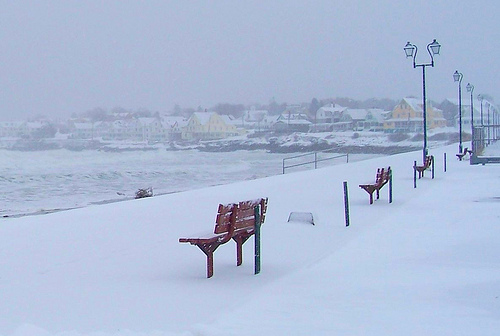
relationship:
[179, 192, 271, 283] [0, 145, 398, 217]
bench near water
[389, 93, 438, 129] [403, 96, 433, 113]
house covered in snow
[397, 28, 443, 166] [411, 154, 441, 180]
lampost by bench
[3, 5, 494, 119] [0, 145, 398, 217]
sky above water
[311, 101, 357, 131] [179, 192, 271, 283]
building not near bench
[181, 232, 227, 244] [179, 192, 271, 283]
snow on bench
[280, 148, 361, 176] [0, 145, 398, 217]
rail near water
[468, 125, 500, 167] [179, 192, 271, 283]
fence near bench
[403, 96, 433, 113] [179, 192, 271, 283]
snow on bench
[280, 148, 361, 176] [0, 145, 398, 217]
rail by water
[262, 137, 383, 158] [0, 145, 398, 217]
rocks are near water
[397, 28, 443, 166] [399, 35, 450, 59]
lampost has lights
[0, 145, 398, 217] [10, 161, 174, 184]
water has waves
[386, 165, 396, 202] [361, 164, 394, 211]
pole behind bench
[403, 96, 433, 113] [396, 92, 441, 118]
snow on top of roof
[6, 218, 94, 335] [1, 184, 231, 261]
snow covering walkway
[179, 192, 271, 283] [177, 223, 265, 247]
bench has a seat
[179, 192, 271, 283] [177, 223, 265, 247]
bench has seat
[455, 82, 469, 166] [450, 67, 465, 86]
post has light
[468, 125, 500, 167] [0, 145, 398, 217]
fence at edge of water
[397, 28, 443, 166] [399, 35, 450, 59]
lampost has two lights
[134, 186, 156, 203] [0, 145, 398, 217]
object laig b water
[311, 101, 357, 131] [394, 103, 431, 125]
building s orage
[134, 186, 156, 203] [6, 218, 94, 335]
object covered with snow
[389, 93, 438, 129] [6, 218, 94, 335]
house covered with snow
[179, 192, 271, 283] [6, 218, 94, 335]
bench covered with snow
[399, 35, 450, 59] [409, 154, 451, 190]
lights are over bench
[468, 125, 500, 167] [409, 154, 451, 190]
fence b bench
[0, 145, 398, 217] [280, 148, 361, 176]
water has rail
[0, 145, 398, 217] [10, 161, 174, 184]
water covered with sow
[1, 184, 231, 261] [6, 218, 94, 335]
walkway covered with snow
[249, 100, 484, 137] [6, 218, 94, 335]
houses are covered with snow